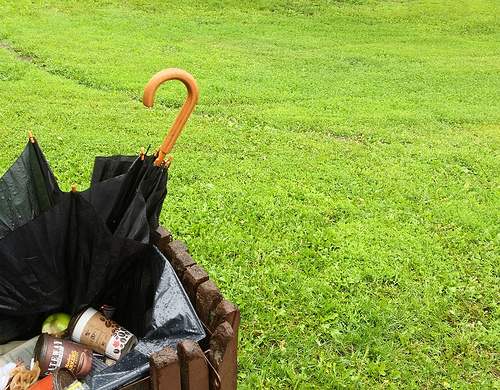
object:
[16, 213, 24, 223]
drops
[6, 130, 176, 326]
canopy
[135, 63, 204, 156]
hook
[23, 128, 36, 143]
spoke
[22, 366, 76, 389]
cup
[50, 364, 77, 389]
lid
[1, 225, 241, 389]
trash bin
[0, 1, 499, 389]
grass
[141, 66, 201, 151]
handle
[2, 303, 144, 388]
trash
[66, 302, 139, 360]
coffee cup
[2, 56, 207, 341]
umbrella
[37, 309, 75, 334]
apple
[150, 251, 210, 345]
trash bag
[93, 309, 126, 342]
design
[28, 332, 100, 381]
cofee cup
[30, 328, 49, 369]
lid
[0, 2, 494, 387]
field